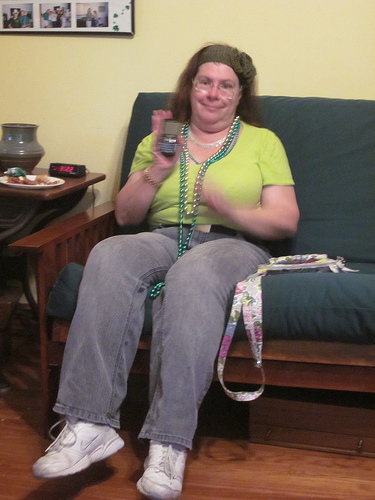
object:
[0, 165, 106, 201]
brown table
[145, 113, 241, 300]
necklace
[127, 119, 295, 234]
shirt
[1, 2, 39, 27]
picture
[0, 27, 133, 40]
frame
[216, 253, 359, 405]
bag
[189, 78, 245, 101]
eyeglass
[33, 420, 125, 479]
shadow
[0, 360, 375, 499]
floor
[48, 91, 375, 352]
futon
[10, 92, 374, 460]
couch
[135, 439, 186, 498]
shoe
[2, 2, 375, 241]
wall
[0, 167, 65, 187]
plate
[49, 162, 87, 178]
alarm clock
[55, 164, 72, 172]
numbers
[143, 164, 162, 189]
bracelet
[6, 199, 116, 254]
arm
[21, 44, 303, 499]
lady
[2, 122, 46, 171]
vase